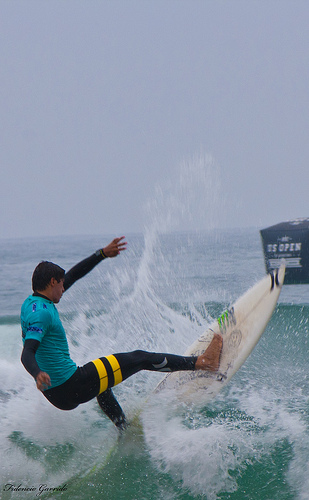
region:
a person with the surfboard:
[25, 265, 279, 438]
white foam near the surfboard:
[77, 287, 241, 464]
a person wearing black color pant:
[56, 346, 200, 399]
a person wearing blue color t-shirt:
[15, 291, 76, 389]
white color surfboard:
[169, 257, 272, 461]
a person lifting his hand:
[80, 237, 133, 276]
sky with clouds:
[77, 139, 271, 207]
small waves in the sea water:
[157, 226, 242, 290]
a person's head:
[32, 260, 69, 301]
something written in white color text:
[265, 236, 303, 255]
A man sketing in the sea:
[8, 255, 227, 400]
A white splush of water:
[148, 410, 232, 480]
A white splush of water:
[247, 380, 303, 496]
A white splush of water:
[140, 271, 192, 332]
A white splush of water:
[11, 395, 105, 477]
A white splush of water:
[146, 199, 203, 319]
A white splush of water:
[71, 294, 135, 352]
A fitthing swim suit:
[16, 277, 209, 416]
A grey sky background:
[118, 167, 234, 225]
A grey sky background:
[8, 146, 78, 230]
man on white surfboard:
[17, 233, 291, 493]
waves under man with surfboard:
[1, 211, 307, 479]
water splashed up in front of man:
[104, 141, 241, 348]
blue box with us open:
[251, 215, 307, 289]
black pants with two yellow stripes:
[45, 347, 195, 433]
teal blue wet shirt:
[13, 301, 78, 389]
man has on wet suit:
[12, 233, 223, 442]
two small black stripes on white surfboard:
[95, 262, 290, 474]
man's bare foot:
[188, 328, 231, 372]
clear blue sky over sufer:
[0, 2, 308, 235]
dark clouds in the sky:
[119, 81, 233, 140]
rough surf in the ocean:
[37, 226, 141, 254]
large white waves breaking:
[99, 283, 201, 331]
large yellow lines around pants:
[89, 350, 126, 392]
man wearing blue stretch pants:
[69, 351, 196, 382]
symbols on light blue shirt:
[19, 299, 54, 318]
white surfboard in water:
[175, 270, 283, 412]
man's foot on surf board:
[188, 337, 235, 378]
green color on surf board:
[206, 304, 249, 326]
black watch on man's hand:
[92, 243, 113, 268]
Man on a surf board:
[17, 249, 293, 417]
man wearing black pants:
[45, 353, 207, 409]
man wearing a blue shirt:
[24, 297, 82, 395]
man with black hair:
[27, 257, 60, 307]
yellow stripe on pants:
[83, 352, 128, 399]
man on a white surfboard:
[171, 255, 304, 451]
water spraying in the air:
[117, 276, 243, 436]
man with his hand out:
[88, 235, 144, 279]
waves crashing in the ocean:
[124, 274, 187, 336]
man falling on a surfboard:
[21, 250, 273, 445]